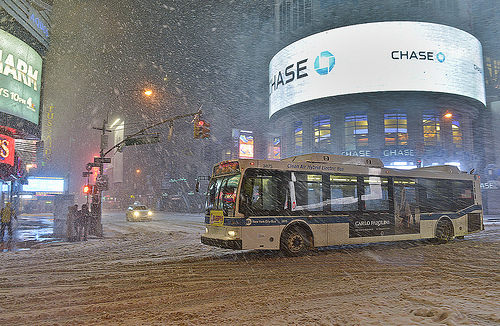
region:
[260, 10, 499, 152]
Chase building lighted by round white sign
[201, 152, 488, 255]
white and blue bus traveling through slushy snow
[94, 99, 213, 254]
metal pole with hanging yellow traffic light showing red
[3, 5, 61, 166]
lighted city center signs in blue and red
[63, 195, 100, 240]
group of people in coats standing on corner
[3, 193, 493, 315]
city streets covered in snow and slush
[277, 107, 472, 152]
lit windows showing blue and yellow interior of Chase bank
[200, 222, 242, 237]
white front lights of bus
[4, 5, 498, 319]
blizzard type winter snow scene with picture taken at night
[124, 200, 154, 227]
single car on road with lights lit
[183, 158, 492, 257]
blue and white bus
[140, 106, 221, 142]
street light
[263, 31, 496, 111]
a billboard advertisement sign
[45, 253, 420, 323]
snow on the street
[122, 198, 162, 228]
a car driving on the street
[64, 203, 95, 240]
pedestrians waiting to cross the street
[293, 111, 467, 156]
windows of the corner building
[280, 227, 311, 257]
tire of the bus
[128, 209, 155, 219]
headlights on the car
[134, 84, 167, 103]
the street light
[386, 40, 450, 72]
The sign says CHASE.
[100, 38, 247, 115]
It is snowing outside.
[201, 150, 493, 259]
There is a bus on the road.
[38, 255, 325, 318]
There is snow on the ground.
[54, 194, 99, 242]
People are by the road.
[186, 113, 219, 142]
The traffic light is red.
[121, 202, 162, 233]
There is a car on the road.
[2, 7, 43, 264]
Large buildings are by the road.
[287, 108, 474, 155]
The lights are purple are yellow.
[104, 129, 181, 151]
The is a street sign on the post.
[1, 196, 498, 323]
The street is snow covered.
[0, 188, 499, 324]
The snow covering is brown.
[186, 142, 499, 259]
The bus is blue and white.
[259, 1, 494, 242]
The Chase building is round.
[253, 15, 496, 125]
The chase sign is blue, white and black.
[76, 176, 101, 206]
The streetlight is red.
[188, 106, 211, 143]
The streetlight is red.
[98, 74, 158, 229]
The streetlamp is on.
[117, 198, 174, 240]
The car has headlights.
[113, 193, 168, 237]
The car's headlights are on.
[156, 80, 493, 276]
a city bus in a snow storm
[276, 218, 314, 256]
the front wheel of a bus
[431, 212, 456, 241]
the rear wheel of a bus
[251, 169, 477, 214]
the windows of a bus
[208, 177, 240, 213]
the windshield of a bus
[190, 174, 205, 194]
the side mirror of a bus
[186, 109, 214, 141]
a city traffic light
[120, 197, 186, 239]
a taxi driving down a snowy street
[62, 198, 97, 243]
three people standing at the corner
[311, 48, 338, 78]
the Chase bank logo